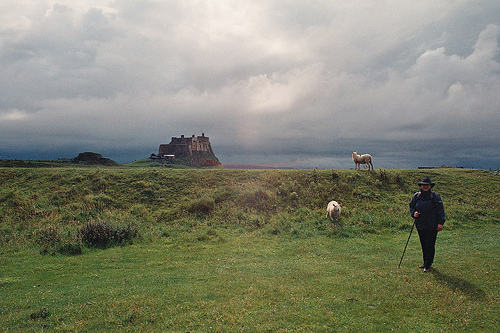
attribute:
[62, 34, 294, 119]
clouds — white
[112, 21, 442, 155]
sky — blue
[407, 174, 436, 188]
hat — black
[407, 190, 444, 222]
shirt — black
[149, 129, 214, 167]
castle — rustic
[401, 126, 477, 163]
waters — blue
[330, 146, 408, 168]
sheep — white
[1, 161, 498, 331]
grass — green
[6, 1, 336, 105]
cloud — white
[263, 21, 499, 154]
cloud — white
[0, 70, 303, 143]
cloud — white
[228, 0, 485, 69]
cloud — white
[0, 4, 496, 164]
sky — blue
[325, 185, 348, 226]
sheep — white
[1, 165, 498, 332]
field — grassy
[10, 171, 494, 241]
hill — little, short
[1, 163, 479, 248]
hill — little